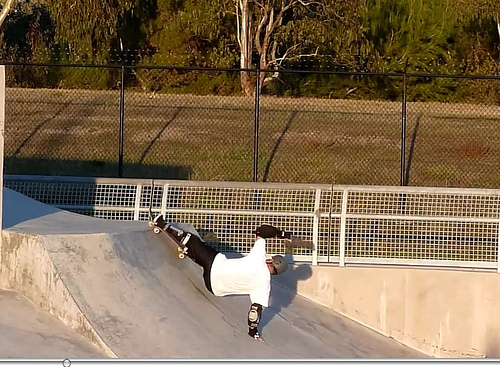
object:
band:
[256, 225, 281, 239]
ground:
[3, 186, 498, 364]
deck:
[7, 192, 141, 233]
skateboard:
[148, 206, 187, 259]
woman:
[153, 214, 292, 343]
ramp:
[0, 224, 429, 365]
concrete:
[6, 186, 401, 365]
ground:
[0, 87, 500, 258]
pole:
[312, 189, 321, 266]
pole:
[161, 184, 168, 220]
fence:
[4, 172, 500, 273]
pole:
[118, 66, 124, 178]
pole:
[252, 71, 260, 183]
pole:
[399, 76, 407, 203]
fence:
[0, 62, 500, 242]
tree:
[353, 1, 470, 96]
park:
[34, 41, 499, 346]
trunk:
[232, 3, 294, 89]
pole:
[339, 188, 348, 267]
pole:
[133, 184, 141, 221]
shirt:
[209, 238, 270, 307]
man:
[152, 214, 293, 343]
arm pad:
[248, 303, 263, 328]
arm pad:
[256, 225, 279, 239]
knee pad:
[179, 231, 192, 245]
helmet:
[272, 255, 288, 275]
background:
[12, 16, 480, 254]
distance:
[14, 10, 484, 125]